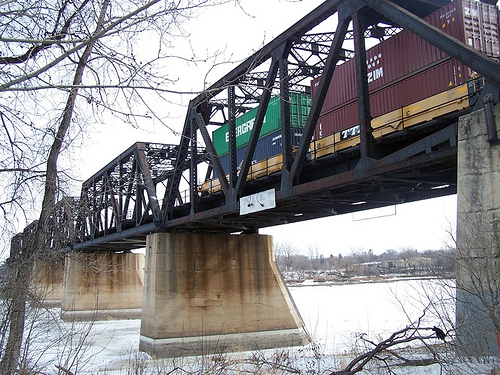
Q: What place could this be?
A: It is a river.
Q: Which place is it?
A: It is a river.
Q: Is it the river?
A: Yes, it is the river.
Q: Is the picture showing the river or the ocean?
A: It is showing the river.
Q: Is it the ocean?
A: No, it is the river.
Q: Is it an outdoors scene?
A: Yes, it is outdoors.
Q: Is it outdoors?
A: Yes, it is outdoors.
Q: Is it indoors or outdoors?
A: It is outdoors.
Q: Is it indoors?
A: No, it is outdoors.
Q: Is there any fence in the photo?
A: No, there are no fences.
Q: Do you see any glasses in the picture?
A: No, there are no glasses.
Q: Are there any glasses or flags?
A: No, there are no glasses or flags.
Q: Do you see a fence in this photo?
A: No, there are no fences.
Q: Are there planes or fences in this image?
A: No, there are no fences or planes.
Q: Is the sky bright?
A: Yes, the sky is bright.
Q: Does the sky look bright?
A: Yes, the sky is bright.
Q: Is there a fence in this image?
A: No, there are no fences.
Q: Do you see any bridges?
A: Yes, there is a bridge.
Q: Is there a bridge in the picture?
A: Yes, there is a bridge.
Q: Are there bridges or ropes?
A: Yes, there is a bridge.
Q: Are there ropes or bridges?
A: Yes, there is a bridge.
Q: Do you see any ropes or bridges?
A: Yes, there is a bridge.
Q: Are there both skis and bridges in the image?
A: No, there is a bridge but no skis.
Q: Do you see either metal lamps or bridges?
A: Yes, there is a metal bridge.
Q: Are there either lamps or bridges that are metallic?
A: Yes, the bridge is metallic.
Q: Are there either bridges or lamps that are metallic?
A: Yes, the bridge is metallic.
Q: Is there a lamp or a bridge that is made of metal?
A: Yes, the bridge is made of metal.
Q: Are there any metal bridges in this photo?
A: Yes, there is a metal bridge.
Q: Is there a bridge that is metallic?
A: Yes, there is a bridge that is metallic.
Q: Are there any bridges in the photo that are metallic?
A: Yes, there is a bridge that is metallic.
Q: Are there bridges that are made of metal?
A: Yes, there is a bridge that is made of metal.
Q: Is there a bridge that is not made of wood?
A: Yes, there is a bridge that is made of metal.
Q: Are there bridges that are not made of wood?
A: Yes, there is a bridge that is made of metal.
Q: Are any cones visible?
A: No, there are no cones.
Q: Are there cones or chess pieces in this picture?
A: No, there are no cones or chess pieces.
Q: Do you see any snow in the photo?
A: Yes, there is snow.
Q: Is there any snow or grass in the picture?
A: Yes, there is snow.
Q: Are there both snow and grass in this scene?
A: No, there is snow but no grass.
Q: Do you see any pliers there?
A: No, there are no pliers.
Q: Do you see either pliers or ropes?
A: No, there are no pliers or ropes.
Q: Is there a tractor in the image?
A: No, there are no tractors.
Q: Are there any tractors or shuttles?
A: No, there are no tractors or shuttles.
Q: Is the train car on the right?
A: Yes, the train car is on the right of the image.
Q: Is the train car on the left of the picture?
A: No, the train car is on the right of the image.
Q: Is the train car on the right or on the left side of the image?
A: The train car is on the right of the image.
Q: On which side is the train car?
A: The train car is on the right of the image.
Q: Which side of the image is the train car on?
A: The train car is on the right of the image.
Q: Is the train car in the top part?
A: Yes, the train car is in the top of the image.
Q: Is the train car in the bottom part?
A: No, the train car is in the top of the image.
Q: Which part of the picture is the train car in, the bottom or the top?
A: The train car is in the top of the image.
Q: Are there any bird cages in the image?
A: No, there are no bird cages.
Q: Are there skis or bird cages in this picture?
A: No, there are no bird cages or skis.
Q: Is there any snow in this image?
A: Yes, there is snow.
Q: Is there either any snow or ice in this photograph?
A: Yes, there is snow.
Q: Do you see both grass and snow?
A: No, there is snow but no grass.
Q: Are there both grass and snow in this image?
A: No, there is snow but no grass.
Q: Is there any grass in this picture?
A: No, there is no grass.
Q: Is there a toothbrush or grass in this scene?
A: No, there are no grass or toothbrushes.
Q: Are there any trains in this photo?
A: Yes, there is a train.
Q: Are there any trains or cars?
A: Yes, there is a train.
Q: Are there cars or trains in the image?
A: Yes, there is a train.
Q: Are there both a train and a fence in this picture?
A: No, there is a train but no fences.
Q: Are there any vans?
A: No, there are no vans.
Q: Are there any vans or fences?
A: No, there are no vans or fences.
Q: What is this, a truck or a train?
A: This is a train.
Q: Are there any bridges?
A: Yes, there is a bridge.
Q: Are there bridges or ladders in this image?
A: Yes, there is a bridge.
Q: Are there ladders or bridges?
A: Yes, there is a bridge.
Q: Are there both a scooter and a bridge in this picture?
A: No, there is a bridge but no scooters.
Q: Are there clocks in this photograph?
A: No, there are no clocks.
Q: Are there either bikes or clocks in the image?
A: No, there are no clocks or bikes.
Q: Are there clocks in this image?
A: No, there are no clocks.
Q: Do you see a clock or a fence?
A: No, there are no clocks or fences.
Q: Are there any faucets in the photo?
A: No, there are no faucets.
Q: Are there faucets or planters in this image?
A: No, there are no faucets or planters.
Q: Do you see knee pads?
A: No, there are no knee pads.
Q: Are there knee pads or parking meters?
A: No, there are no knee pads or parking meters.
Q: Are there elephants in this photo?
A: No, there are no elephants.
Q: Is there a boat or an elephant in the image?
A: No, there are no elephants or boats.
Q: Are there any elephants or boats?
A: No, there are no elephants or boats.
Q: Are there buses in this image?
A: No, there are no buses.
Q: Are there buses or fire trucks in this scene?
A: No, there are no buses or fire trucks.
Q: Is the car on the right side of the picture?
A: Yes, the car is on the right of the image.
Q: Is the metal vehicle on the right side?
A: Yes, the car is on the right of the image.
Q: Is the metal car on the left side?
A: No, the car is on the right of the image.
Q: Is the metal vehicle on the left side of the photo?
A: No, the car is on the right of the image.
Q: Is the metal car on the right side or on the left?
A: The car is on the right of the image.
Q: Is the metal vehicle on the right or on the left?
A: The car is on the right of the image.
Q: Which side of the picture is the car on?
A: The car is on the right of the image.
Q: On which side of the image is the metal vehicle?
A: The car is on the right of the image.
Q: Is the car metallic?
A: Yes, the car is metallic.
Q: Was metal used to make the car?
A: Yes, the car is made of metal.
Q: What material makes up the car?
A: The car is made of metal.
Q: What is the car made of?
A: The car is made of metal.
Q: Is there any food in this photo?
A: No, there is no food.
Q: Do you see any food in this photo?
A: No, there is no food.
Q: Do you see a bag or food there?
A: No, there are no food or bags.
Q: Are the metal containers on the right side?
A: Yes, the containers are on the right of the image.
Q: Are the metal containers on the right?
A: Yes, the containers are on the right of the image.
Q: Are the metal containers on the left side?
A: No, the containers are on the right of the image.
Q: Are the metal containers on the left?
A: No, the containers are on the right of the image.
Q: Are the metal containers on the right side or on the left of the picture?
A: The containers are on the right of the image.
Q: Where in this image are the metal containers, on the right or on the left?
A: The containers are on the right of the image.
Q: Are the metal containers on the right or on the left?
A: The containers are on the right of the image.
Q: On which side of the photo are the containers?
A: The containers are on the right of the image.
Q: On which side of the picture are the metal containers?
A: The containers are on the right of the image.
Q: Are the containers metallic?
A: Yes, the containers are metallic.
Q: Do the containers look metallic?
A: Yes, the containers are metallic.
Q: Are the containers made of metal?
A: Yes, the containers are made of metal.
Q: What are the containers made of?
A: The containers are made of metal.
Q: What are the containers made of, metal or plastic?
A: The containers are made of metal.